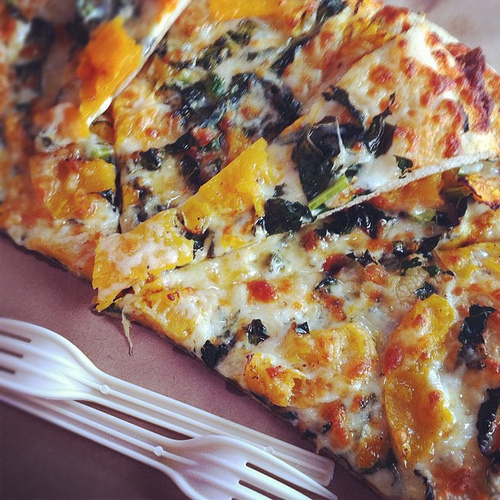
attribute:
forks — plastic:
[1, 316, 335, 487]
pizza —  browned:
[311, 77, 498, 197]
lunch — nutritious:
[1, 0, 499, 498]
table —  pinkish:
[9, 263, 284, 425]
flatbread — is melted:
[24, 27, 494, 434]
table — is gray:
[4, 3, 499, 498]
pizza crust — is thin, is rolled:
[424, 22, 497, 154]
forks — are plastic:
[6, 329, 321, 497]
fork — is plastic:
[13, 320, 349, 487]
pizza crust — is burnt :
[455, 48, 491, 121]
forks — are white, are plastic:
[2, 308, 347, 497]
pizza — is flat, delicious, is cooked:
[2, 1, 499, 498]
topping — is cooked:
[192, 131, 282, 230]